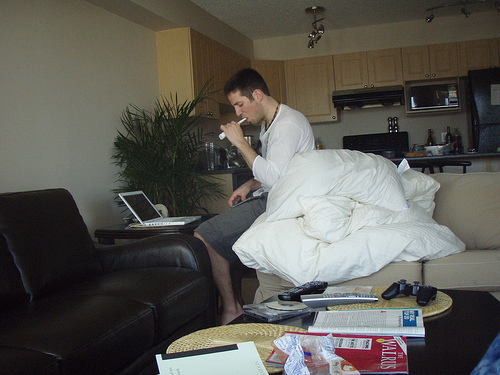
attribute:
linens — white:
[231, 147, 464, 288]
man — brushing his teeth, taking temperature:
[195, 68, 318, 329]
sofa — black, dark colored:
[1, 188, 218, 373]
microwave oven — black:
[408, 82, 461, 110]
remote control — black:
[281, 281, 328, 304]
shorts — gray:
[196, 197, 266, 264]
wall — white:
[2, 2, 159, 244]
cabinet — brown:
[335, 49, 401, 91]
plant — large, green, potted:
[111, 75, 219, 223]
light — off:
[306, 5, 324, 51]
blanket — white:
[232, 149, 465, 290]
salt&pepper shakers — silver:
[387, 117, 398, 133]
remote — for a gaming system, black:
[382, 280, 437, 305]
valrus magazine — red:
[263, 331, 408, 375]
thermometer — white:
[218, 118, 246, 141]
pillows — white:
[266, 150, 410, 222]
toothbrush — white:
[219, 120, 243, 140]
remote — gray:
[301, 292, 377, 307]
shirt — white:
[246, 101, 316, 197]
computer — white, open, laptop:
[118, 187, 203, 228]